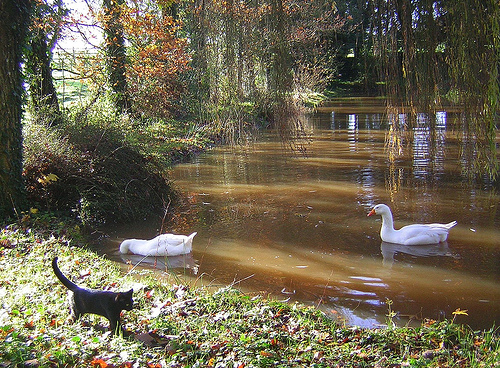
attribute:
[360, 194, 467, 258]
duck — white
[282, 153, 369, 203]
water — brown, murky, calm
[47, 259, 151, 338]
cat — black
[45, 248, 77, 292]
tail — long, log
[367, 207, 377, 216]
beak — orange